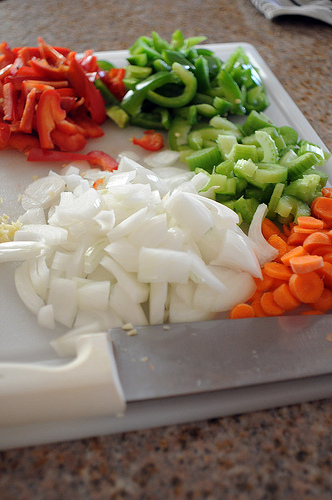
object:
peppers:
[0, 36, 164, 172]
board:
[0, 42, 332, 451]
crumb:
[121, 322, 169, 370]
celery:
[185, 109, 327, 224]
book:
[251, 0, 331, 28]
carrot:
[230, 186, 332, 319]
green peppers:
[92, 27, 269, 152]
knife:
[0, 314, 332, 426]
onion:
[0, 155, 279, 358]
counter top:
[0, 451, 332, 500]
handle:
[0, 329, 126, 425]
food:
[0, 26, 332, 359]